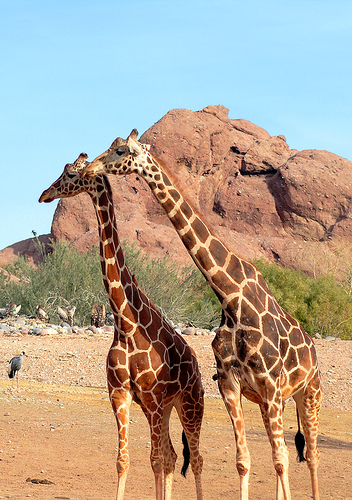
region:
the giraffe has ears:
[94, 124, 159, 195]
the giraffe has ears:
[59, 101, 209, 249]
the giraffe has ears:
[71, 82, 158, 202]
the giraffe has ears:
[87, 112, 193, 216]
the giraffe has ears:
[97, 123, 280, 270]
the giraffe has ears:
[91, 76, 215, 195]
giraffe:
[102, 127, 157, 192]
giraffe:
[36, 153, 85, 205]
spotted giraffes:
[24, 122, 311, 478]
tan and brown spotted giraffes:
[31, 128, 288, 474]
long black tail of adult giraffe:
[292, 423, 302, 463]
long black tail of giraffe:
[176, 429, 189, 482]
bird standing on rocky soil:
[5, 341, 29, 386]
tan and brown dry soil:
[9, 393, 88, 467]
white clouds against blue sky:
[11, 8, 319, 97]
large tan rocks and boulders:
[219, 140, 307, 237]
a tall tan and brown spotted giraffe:
[37, 153, 204, 497]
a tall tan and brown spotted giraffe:
[83, 128, 323, 499]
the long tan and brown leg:
[105, 352, 137, 499]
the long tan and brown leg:
[136, 380, 170, 498]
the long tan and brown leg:
[154, 404, 177, 499]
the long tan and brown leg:
[176, 388, 210, 497]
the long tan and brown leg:
[220, 368, 253, 498]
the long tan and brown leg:
[259, 382, 293, 499]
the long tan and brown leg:
[297, 382, 322, 498]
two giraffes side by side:
[24, 120, 333, 457]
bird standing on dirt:
[4, 347, 43, 397]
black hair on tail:
[288, 426, 306, 468]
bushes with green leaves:
[286, 261, 334, 309]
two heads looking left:
[35, 129, 151, 217]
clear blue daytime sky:
[224, 8, 301, 68]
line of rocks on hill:
[29, 317, 110, 338]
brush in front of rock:
[29, 222, 83, 283]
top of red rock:
[160, 101, 248, 142]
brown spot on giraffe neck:
[111, 281, 132, 313]